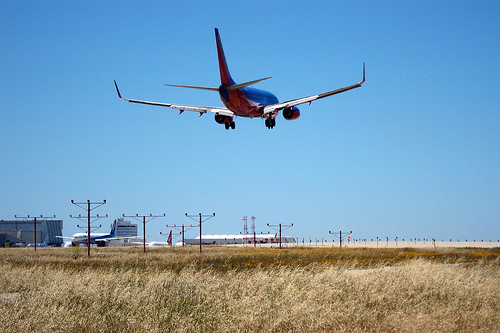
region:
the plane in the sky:
[110, 14, 428, 139]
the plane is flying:
[63, 10, 407, 175]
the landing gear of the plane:
[213, 117, 279, 135]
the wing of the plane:
[258, 48, 413, 138]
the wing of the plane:
[95, 71, 225, 136]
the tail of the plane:
[165, 0, 312, 100]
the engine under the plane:
[275, 105, 306, 121]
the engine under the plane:
[213, 111, 230, 125]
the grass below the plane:
[119, 266, 451, 331]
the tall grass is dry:
[120, 278, 382, 318]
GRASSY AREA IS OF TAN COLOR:
[5, 248, 497, 325]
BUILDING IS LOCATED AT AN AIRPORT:
[4, 214, 64, 254]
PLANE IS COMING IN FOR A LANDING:
[107, 23, 367, 130]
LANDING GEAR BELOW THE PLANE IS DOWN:
[214, 115, 284, 128]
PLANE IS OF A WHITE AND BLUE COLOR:
[70, 220, 154, 251]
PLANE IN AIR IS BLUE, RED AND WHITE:
[113, 29, 373, 131]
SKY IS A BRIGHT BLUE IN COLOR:
[0, 3, 493, 222]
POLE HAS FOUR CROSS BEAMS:
[70, 200, 110, 254]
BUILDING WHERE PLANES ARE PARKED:
[193, 228, 299, 250]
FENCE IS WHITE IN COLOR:
[216, 236, 497, 253]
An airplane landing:
[103, 20, 388, 135]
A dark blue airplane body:
[183, 7, 290, 114]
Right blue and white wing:
[256, 66, 377, 123]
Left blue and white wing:
[109, 79, 205, 125]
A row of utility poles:
[68, 192, 216, 242]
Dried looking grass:
[42, 263, 381, 318]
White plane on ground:
[59, 224, 119, 246]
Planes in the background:
[138, 230, 177, 247]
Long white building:
[202, 223, 292, 242]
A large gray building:
[4, 215, 72, 249]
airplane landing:
[106, 24, 370, 135]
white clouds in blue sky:
[402, 10, 469, 85]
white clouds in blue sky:
[404, 98, 464, 134]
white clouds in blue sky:
[360, 152, 439, 208]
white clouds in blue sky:
[241, 169, 289, 214]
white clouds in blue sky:
[24, 116, 58, 158]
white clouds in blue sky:
[41, 45, 76, 113]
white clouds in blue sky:
[116, 20, 144, 42]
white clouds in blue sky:
[33, 4, 79, 72]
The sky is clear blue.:
[5, 5, 496, 232]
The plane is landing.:
[103, 30, 380, 131]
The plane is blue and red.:
[93, 28, 381, 142]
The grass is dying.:
[5, 239, 483, 331]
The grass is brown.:
[0, 242, 496, 330]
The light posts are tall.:
[21, 189, 439, 265]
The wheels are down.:
[207, 108, 304, 129]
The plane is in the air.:
[101, 17, 371, 133]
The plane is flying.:
[78, 32, 388, 147]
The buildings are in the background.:
[0, 218, 139, 253]